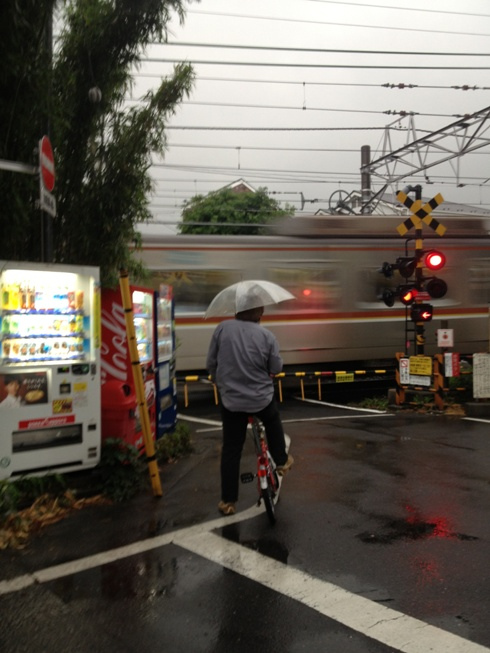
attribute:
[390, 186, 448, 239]
sign — yellow, black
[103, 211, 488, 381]
train — speeding, gray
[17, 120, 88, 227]
sign — red, white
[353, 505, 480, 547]
puddle — water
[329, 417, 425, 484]
puddle — water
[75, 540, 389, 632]
puddle — water